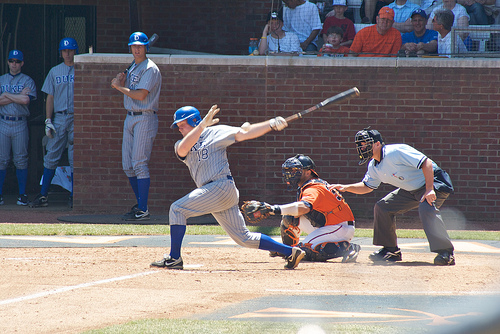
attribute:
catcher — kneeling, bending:
[241, 151, 361, 266]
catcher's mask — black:
[280, 157, 303, 189]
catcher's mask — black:
[353, 126, 375, 167]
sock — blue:
[170, 221, 187, 261]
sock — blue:
[257, 230, 293, 261]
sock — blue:
[127, 175, 154, 209]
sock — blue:
[40, 163, 59, 195]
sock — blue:
[13, 164, 32, 196]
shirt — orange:
[294, 176, 358, 226]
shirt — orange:
[349, 23, 403, 56]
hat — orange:
[375, 5, 397, 21]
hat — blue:
[409, 7, 428, 19]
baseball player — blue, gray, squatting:
[150, 102, 306, 269]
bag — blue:
[434, 167, 456, 194]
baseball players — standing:
[1, 29, 164, 224]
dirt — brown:
[1, 244, 499, 334]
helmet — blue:
[168, 104, 204, 132]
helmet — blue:
[126, 30, 151, 50]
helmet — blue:
[55, 35, 81, 56]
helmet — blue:
[5, 46, 25, 64]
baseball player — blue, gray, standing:
[110, 29, 165, 222]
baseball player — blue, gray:
[36, 34, 78, 211]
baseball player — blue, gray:
[0, 47, 33, 208]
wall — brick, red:
[73, 56, 499, 225]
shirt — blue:
[401, 29, 439, 56]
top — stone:
[73, 46, 499, 69]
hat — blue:
[60, 38, 78, 53]